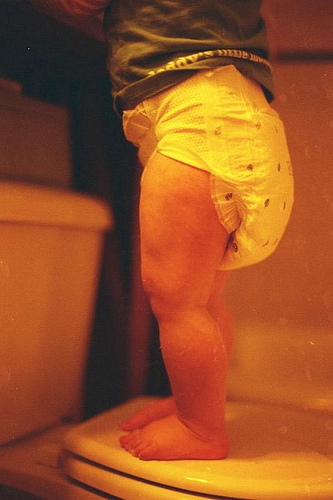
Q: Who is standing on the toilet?
A: A baby.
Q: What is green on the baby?
A: His tshirt.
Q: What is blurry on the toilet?
A: A box of tissues.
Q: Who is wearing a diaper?
A: A toddler.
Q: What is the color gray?
A: A part of a shirt.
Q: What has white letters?
A: The shirt.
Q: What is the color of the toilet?
A: White.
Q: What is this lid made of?
A: Plastic.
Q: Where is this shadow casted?
A: On toilet.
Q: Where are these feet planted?
A: On toilet.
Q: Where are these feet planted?
A: Toilet.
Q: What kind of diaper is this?
A: Disposable.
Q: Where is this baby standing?
A: On toilet.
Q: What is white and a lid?
A: The toilet lid.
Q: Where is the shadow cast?
A: On the toilet lid.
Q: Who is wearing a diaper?
A: A toddler.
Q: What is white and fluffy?
A: The diaper.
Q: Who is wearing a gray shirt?
A: A toddler.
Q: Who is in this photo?
A: A child.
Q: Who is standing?
A: A child.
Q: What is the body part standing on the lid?
A: A leg.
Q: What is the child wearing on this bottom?
A: Diaper.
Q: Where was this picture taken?
A: Bathroom.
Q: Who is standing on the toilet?
A: A baby.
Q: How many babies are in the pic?
A: 1.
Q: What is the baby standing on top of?
A: A toilet.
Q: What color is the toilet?
A: White.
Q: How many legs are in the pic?
A: 2.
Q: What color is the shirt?
A: Gray.